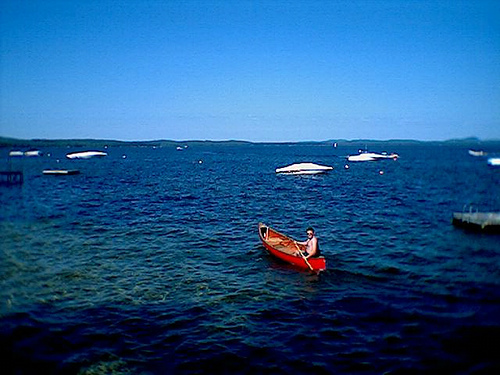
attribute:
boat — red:
[250, 217, 332, 277]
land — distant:
[318, 135, 479, 146]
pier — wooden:
[448, 202, 498, 233]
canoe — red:
[259, 223, 327, 277]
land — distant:
[3, 135, 498, 147]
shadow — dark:
[2, 272, 499, 371]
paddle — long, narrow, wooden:
[289, 236, 319, 274]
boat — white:
[274, 161, 334, 179]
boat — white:
[271, 156, 335, 181]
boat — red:
[256, 226, 311, 263]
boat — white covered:
[271, 161, 338, 185]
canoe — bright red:
[255, 223, 327, 271]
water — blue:
[131, 132, 244, 268]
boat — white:
[278, 154, 331, 176]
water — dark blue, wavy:
[0, 138, 500, 373]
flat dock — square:
[42, 167, 79, 174]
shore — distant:
[1, 134, 499, 146]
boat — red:
[256, 219, 319, 287]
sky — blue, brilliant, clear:
[1, 2, 498, 143]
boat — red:
[227, 217, 364, 297]